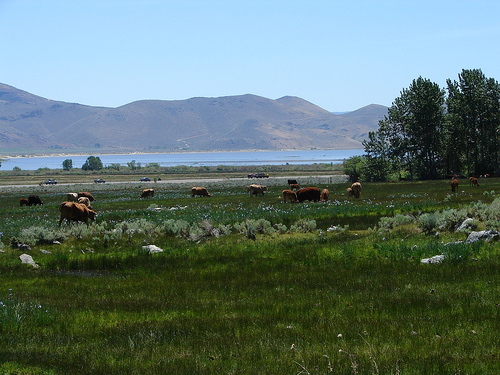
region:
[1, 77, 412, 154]
Distant mountains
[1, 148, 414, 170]
Blue river or lake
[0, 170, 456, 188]
Highway with cars driving on it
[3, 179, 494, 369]
Field with cows grazing in it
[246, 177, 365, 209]
Cattle grazing in a field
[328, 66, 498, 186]
Trees alongside a field and highway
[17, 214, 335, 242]
White plants in a field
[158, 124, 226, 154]
Path going between two mountains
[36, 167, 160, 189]
Cars driving down a highway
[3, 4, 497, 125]
Light blue sky above mountains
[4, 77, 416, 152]
Mountains in the distance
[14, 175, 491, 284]
cows grazing in a field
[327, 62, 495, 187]
a group of green trees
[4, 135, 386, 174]
a river at bottom of the mountain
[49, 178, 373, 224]
group of brown cows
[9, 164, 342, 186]
a line of cars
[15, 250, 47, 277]
large white rock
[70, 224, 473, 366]
tall green grass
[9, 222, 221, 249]
white flowers in middle of field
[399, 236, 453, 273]
A white rock in a field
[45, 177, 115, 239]
Cows grazing in a field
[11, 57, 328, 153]
A line of hills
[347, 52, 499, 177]
A grouping of evergreen trees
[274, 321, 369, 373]
Wildflowers in a field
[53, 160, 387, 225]
A number of cows in a field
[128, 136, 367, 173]
A lake from far away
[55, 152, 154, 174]
Trees along a lake side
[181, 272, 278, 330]
Tall grass in a field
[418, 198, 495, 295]
A grouping of rocks in a field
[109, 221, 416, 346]
green grass in a pasture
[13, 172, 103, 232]
a group of six cows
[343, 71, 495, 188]
green trees in the pasture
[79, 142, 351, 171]
a blue lake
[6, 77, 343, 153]
mountain in the distance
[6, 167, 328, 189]
cars driving along a road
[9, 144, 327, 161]
shore line of the lake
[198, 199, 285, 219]
white flowers in the pasture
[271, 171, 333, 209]
grazing cattle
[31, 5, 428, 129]
clear blue sky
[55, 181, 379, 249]
Cows grazing in open field.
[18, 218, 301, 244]
Scrub bush growing in field.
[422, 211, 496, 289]
Rocks laying in field.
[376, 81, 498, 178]
Pine trees growing next to field.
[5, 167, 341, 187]
Cars traveling on road.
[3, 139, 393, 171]
Lake across road from field.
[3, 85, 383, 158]
Mountains next to lake.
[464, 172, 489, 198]
A cow grazing alone.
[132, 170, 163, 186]
A blue car on road.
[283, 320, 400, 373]
Scraggly flowers growing in field.